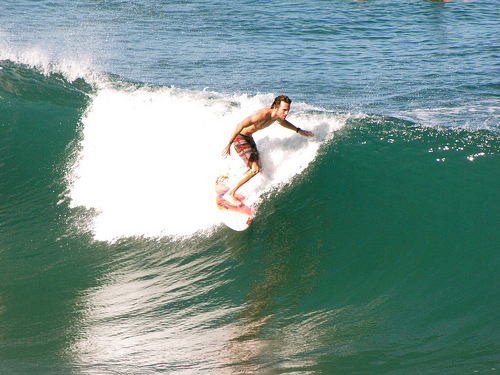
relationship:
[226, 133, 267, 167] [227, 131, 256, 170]
shorts with stripe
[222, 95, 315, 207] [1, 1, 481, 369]
man swimming in water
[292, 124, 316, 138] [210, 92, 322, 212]
hand of person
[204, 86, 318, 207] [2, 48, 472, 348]
man touching water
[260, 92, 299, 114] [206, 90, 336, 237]
hair on person